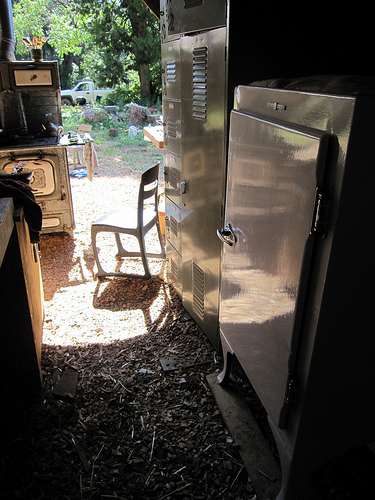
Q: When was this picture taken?
A: Daytime.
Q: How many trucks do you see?
A: 1.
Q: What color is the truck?
A: White.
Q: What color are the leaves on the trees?
A: Green.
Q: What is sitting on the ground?
A: A chair.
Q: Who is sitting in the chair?
A: No one.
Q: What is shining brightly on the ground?
A: Sunlight.